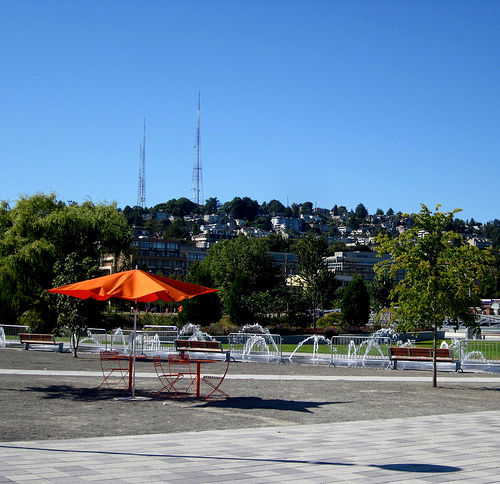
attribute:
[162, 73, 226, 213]
pole — tall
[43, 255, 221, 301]
umbrella — orange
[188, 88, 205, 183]
tower — tall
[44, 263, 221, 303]
umbrella — orange 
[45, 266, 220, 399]
umbrella — large, bright, orange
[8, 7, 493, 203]
sky — clear, blue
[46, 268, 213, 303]
umbrella — orange 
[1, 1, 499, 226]
cloudless sky — bloudless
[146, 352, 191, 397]
chairs — orange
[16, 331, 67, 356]
bench — brown 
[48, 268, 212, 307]
umbrella — orange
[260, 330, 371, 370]
water — spouting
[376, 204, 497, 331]
tree top — dark green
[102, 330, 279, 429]
table — orange